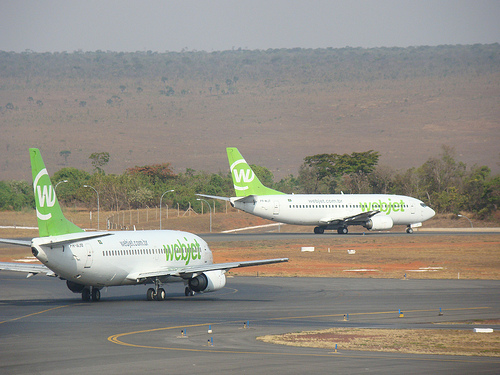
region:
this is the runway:
[41, 304, 148, 358]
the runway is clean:
[29, 317, 113, 367]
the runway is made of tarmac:
[45, 320, 127, 373]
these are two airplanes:
[28, 133, 445, 297]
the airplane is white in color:
[259, 196, 279, 214]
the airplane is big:
[16, 147, 295, 306]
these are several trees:
[126, 170, 196, 203]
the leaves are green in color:
[325, 155, 370, 172]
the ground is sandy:
[393, 249, 427, 269]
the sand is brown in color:
[402, 237, 427, 247]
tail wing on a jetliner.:
[218, 139, 296, 196]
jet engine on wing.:
[177, 261, 247, 308]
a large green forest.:
[0, 42, 497, 88]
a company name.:
[155, 235, 205, 267]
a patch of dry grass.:
[252, 320, 498, 367]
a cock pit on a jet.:
[415, 200, 437, 220]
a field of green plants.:
[0, 146, 498, 213]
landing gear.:
[138, 272, 172, 304]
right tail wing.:
[36, 211, 121, 265]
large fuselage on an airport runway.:
[217, 179, 445, 216]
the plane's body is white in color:
[31, 228, 216, 296]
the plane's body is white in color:
[230, 192, 440, 223]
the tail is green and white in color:
[29, 146, 89, 236]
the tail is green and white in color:
[223, 145, 283, 198]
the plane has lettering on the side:
[161, 239, 208, 268]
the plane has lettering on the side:
[358, 196, 413, 213]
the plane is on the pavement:
[8, 145, 290, 306]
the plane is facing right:
[194, 141, 434, 241]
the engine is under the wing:
[186, 268, 227, 292]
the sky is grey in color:
[1, 2, 498, 50]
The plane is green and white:
[206, 141, 442, 238]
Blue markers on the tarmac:
[188, 319, 270, 356]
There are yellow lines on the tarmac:
[30, 269, 492, 365]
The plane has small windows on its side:
[96, 241, 212, 263]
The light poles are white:
[77, 162, 224, 242]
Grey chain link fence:
[105, 197, 215, 236]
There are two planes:
[8, 105, 444, 318]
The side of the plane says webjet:
[148, 221, 220, 281]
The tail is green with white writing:
[18, 155, 93, 252]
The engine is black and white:
[176, 267, 242, 293]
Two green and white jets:
[11, 126, 441, 311]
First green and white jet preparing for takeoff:
[182, 140, 442, 245]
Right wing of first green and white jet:
[330, 200, 395, 235]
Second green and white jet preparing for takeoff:
[2, 141, 294, 304]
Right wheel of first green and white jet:
[331, 218, 358, 243]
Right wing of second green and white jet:
[122, 253, 300, 284]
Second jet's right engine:
[177, 270, 233, 297]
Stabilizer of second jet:
[22, 142, 88, 242]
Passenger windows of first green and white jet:
[281, 195, 413, 210]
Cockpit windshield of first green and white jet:
[412, 192, 434, 214]